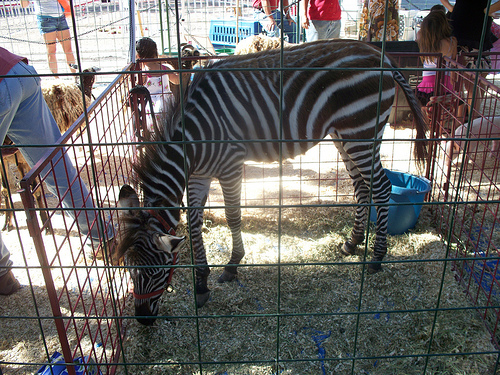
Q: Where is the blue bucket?
A: In zebra's cage.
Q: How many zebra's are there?
A: 1.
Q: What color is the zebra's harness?
A: Red.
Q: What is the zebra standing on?
A: Hay.